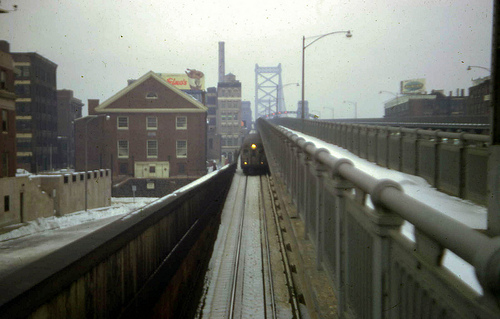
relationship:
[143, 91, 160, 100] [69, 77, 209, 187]
window on building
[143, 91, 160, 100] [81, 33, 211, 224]
window on building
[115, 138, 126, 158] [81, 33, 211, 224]
window on building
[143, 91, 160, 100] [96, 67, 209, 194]
window attached to building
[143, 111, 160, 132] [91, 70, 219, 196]
glass on building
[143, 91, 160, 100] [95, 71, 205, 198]
window in building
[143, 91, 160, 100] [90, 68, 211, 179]
window on building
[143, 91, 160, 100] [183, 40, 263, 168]
window in building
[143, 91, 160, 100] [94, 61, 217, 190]
window in building